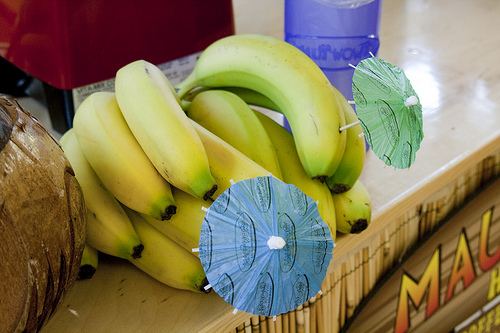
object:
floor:
[368, 0, 500, 215]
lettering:
[392, 208, 499, 332]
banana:
[188, 90, 282, 181]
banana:
[181, 31, 347, 179]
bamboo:
[230, 154, 499, 332]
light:
[402, 66, 440, 114]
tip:
[405, 96, 419, 106]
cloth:
[1, 1, 235, 88]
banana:
[71, 91, 175, 220]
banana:
[114, 60, 218, 199]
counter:
[0, 0, 499, 333]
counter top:
[0, 0, 499, 333]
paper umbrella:
[354, 57, 422, 167]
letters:
[392, 245, 440, 333]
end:
[162, 206, 176, 221]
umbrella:
[200, 175, 335, 316]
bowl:
[1, 86, 87, 332]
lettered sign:
[341, 177, 497, 332]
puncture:
[338, 128, 342, 133]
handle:
[338, 121, 361, 131]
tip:
[267, 236, 286, 249]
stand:
[0, 0, 234, 134]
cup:
[284, 1, 378, 130]